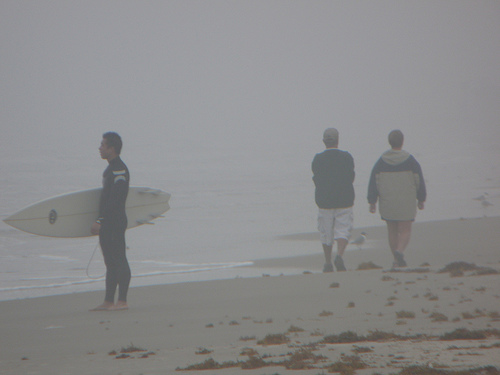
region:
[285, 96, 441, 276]
couple walking on the beach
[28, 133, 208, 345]
surfer standing on the shore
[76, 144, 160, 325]
surfer wearing black wetsuit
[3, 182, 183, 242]
surfer carrying surfboard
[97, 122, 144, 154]
surfer has short black hair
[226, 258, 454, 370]
sand is wet and dense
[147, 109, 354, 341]
ocean is foggy and dark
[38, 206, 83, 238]
surfboard has logo on it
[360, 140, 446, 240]
woman wearing black and tan jacket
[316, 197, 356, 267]
man wearing white shorts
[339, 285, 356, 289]
part of a beach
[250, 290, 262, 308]
edge of a beach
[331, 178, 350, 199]
back of a man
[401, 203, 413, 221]
jacket of a man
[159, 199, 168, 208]
part of a board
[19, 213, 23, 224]
tip of a board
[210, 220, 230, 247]
part of the ocean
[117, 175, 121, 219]
part of a shoulder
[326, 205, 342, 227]
part of a short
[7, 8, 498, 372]
scene takes place on beach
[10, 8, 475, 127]
it is foggy outside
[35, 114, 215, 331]
man holding a surfboard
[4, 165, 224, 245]
the surfboard is white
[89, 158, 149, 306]
man wearing a wetsuit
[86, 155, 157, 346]
the wetsuit is black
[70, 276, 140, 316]
man not wearing shoes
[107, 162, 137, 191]
white letters on man's suit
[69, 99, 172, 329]
man is looking at ocean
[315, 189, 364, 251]
man is wearing shorts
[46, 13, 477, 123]
The sky is very cloudy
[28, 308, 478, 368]
The beach has seaweed on it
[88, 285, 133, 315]
The feet of the surfer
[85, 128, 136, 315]
The man has on a wet suit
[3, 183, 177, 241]
The surfboard is white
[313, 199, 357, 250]
The man is wearing white shorts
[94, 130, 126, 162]
The man has brown hair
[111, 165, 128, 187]
The logo on the wet suit is white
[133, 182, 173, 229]
The end of the surfboard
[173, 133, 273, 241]
The water in the ocean is calm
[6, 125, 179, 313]
surfer standing on sand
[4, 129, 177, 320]
man holding white surfboard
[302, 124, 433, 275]
people walking on beach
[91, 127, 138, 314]
man looking out at water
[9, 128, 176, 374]
surfer on beach with fog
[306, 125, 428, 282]
people walking in fog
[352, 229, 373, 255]
bird by water's edge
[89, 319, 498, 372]
beach with washed up seaweed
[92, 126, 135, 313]
barefoot man in wetsuit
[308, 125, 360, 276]
person wearing white pants